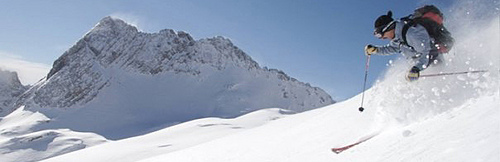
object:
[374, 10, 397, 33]
hat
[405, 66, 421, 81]
gloves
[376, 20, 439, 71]
jacket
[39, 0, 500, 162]
snow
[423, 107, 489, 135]
ground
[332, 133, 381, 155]
ski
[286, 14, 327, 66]
sky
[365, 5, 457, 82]
man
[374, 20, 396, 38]
goggles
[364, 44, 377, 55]
glove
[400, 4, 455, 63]
backpack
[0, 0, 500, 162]
ski slope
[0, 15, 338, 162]
hill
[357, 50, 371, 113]
pole